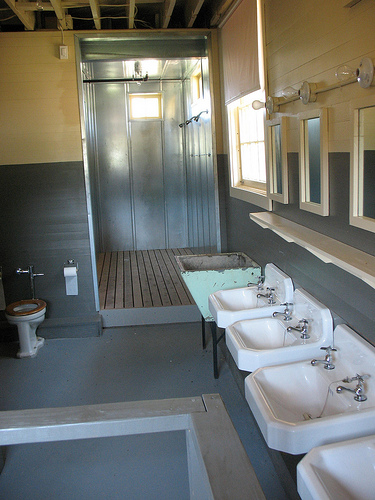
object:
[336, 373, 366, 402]
faucet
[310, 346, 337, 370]
faucet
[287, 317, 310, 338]
faucet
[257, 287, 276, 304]
faucet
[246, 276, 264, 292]
faucet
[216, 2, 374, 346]
wall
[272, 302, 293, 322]
faucet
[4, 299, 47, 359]
toilet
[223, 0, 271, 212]
window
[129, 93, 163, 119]
window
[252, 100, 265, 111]
light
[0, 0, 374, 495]
bathroom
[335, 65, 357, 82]
bulb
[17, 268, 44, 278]
handle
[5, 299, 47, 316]
seat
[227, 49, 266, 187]
view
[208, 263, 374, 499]
sinks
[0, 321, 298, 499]
floor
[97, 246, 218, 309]
wood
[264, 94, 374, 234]
mirrors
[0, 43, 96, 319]
wall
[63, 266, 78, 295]
roll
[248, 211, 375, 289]
shelf